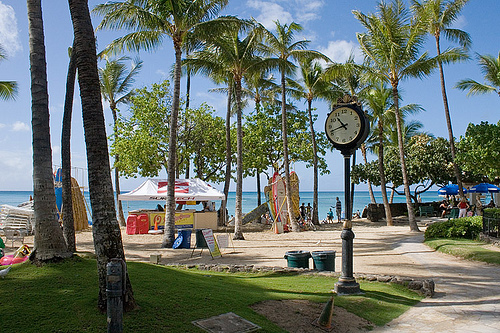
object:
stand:
[115, 175, 229, 230]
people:
[324, 205, 333, 224]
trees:
[264, 52, 346, 226]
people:
[351, 208, 363, 221]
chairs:
[1, 209, 36, 251]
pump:
[104, 257, 126, 332]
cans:
[284, 250, 312, 270]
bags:
[310, 250, 337, 260]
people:
[435, 199, 450, 220]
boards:
[263, 171, 288, 236]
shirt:
[457, 201, 467, 210]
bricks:
[247, 300, 378, 330]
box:
[135, 213, 149, 234]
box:
[127, 214, 136, 236]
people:
[298, 202, 307, 225]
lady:
[455, 196, 469, 220]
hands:
[464, 207, 468, 210]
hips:
[463, 202, 470, 208]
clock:
[323, 103, 371, 155]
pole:
[335, 153, 360, 294]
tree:
[350, 0, 471, 235]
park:
[0, 0, 499, 331]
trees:
[169, 16, 298, 241]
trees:
[91, 0, 258, 248]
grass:
[0, 254, 424, 331]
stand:
[333, 152, 360, 297]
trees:
[241, 19, 337, 232]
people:
[471, 195, 486, 218]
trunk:
[66, 0, 138, 313]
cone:
[309, 293, 337, 331]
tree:
[62, 49, 76, 255]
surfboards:
[61, 178, 89, 232]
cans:
[310, 250, 337, 272]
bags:
[283, 250, 311, 259]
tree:
[407, 0, 474, 196]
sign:
[149, 212, 192, 225]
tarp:
[118, 177, 227, 202]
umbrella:
[437, 184, 466, 202]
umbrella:
[462, 181, 499, 198]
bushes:
[424, 215, 484, 239]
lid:
[308, 250, 336, 261]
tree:
[66, 0, 137, 313]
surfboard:
[285, 172, 299, 230]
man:
[333, 194, 341, 224]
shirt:
[334, 201, 342, 214]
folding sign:
[200, 228, 223, 259]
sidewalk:
[0, 217, 499, 332]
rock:
[257, 266, 272, 273]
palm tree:
[241, 18, 335, 233]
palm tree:
[169, 14, 298, 241]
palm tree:
[89, 0, 254, 248]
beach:
[0, 202, 499, 331]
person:
[303, 202, 313, 226]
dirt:
[250, 258, 375, 299]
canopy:
[118, 177, 227, 202]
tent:
[114, 176, 226, 234]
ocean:
[0, 189, 499, 222]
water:
[0, 191, 495, 222]